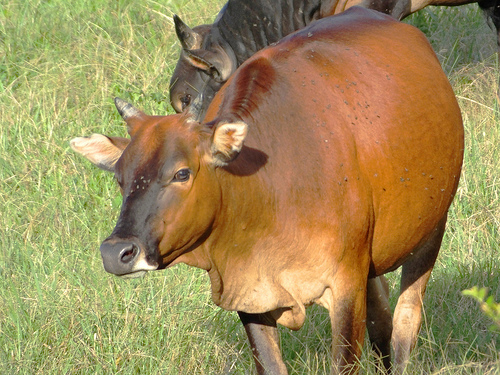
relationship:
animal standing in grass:
[189, 7, 468, 74] [30, 221, 84, 317]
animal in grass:
[68, 6, 464, 375] [3, 4, 498, 363]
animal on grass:
[68, 6, 464, 375] [3, 4, 498, 363]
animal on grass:
[167, 0, 499, 115] [3, 4, 498, 363]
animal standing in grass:
[68, 6, 464, 375] [3, 4, 498, 363]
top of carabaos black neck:
[219, 49, 238, 58] [218, 4, 285, 30]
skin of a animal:
[72, 8, 464, 371] [68, 6, 464, 375]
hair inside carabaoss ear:
[224, 126, 233, 168] [165, 87, 289, 201]